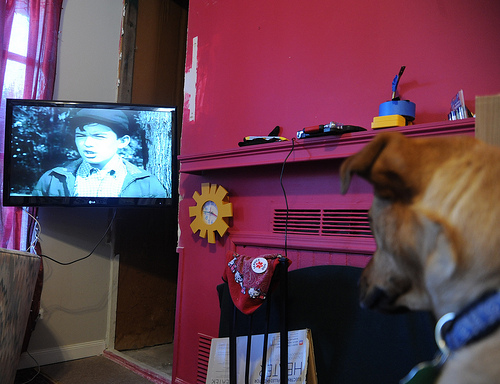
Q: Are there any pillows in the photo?
A: No, there are no pillows.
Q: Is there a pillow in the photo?
A: No, there are no pillows.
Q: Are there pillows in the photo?
A: No, there are no pillows.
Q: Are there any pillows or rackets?
A: No, there are no pillows or rackets.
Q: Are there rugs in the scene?
A: No, there are no rugs.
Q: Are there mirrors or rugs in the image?
A: No, there are no rugs or mirrors.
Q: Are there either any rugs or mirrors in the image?
A: No, there are no rugs or mirrors.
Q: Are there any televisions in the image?
A: Yes, there is a television.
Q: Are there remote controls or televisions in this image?
A: Yes, there is a television.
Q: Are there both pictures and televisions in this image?
A: No, there is a television but no pictures.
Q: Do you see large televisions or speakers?
A: Yes, there is a large television.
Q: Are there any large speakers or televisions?
A: Yes, there is a large television.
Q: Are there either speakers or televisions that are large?
A: Yes, the television is large.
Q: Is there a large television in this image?
A: Yes, there is a large television.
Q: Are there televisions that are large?
A: Yes, there is a television that is large.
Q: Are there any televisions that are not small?
A: Yes, there is a large television.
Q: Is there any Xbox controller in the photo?
A: No, there are no Xbox controllers.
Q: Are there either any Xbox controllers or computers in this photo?
A: No, there are no Xbox controllers or computers.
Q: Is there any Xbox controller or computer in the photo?
A: No, there are no Xbox controllers or computers.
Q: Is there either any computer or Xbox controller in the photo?
A: No, there are no Xbox controllers or computers.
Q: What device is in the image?
A: The device is a television.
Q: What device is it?
A: The device is a television.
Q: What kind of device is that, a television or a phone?
A: This is a television.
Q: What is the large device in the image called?
A: The device is a television.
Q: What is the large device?
A: The device is a television.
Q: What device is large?
A: The device is a television.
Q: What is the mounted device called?
A: The device is a television.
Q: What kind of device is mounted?
A: The device is a television.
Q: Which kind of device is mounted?
A: The device is a television.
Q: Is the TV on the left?
A: Yes, the TV is on the left of the image.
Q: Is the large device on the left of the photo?
A: Yes, the TV is on the left of the image.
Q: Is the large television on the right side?
A: No, the TV is on the left of the image.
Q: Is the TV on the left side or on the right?
A: The TV is on the left of the image.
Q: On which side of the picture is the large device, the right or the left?
A: The TV is on the left of the image.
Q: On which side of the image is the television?
A: The television is on the left of the image.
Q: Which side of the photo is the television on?
A: The television is on the left of the image.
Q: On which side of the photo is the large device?
A: The television is on the left of the image.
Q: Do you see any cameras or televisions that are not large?
A: No, there is a television but it is large.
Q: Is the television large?
A: Yes, the television is large.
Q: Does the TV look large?
A: Yes, the TV is large.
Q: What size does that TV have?
A: The TV has large size.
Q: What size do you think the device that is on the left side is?
A: The TV is large.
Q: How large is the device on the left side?
A: The television is large.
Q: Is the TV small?
A: No, the TV is large.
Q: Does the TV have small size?
A: No, the TV is large.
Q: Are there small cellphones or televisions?
A: No, there is a television but it is large.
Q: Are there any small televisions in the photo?
A: No, there is a television but it is large.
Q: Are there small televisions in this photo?
A: No, there is a television but it is large.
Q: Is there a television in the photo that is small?
A: No, there is a television but it is large.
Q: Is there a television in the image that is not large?
A: No, there is a television but it is large.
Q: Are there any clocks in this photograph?
A: Yes, there is a clock.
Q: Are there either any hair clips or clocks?
A: Yes, there is a clock.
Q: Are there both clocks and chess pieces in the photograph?
A: No, there is a clock but no chess pieces.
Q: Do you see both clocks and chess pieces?
A: No, there is a clock but no chess pieces.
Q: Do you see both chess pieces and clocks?
A: No, there is a clock but no chess pieces.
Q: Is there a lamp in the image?
A: No, there are no lamps.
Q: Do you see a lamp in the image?
A: No, there are no lamps.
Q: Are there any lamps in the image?
A: No, there are no lamps.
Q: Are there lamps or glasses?
A: No, there are no lamps or glasses.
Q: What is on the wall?
A: The clock is on the wall.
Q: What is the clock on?
A: The clock is on the wall.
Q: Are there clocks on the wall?
A: Yes, there is a clock on the wall.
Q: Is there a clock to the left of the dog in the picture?
A: Yes, there is a clock to the left of the dog.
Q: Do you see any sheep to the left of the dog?
A: No, there is a clock to the left of the dog.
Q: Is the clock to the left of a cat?
A: No, the clock is to the left of the dog.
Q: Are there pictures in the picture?
A: No, there are no pictures.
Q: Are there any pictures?
A: No, there are no pictures.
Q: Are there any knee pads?
A: No, there are no knee pads.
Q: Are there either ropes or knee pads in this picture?
A: No, there are no knee pads or ropes.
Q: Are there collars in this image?
A: Yes, there is a collar.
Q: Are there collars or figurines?
A: Yes, there is a collar.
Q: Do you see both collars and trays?
A: No, there is a collar but no trays.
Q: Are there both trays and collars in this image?
A: No, there is a collar but no trays.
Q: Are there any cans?
A: No, there are no cans.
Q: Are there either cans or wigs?
A: No, there are no cans or wigs.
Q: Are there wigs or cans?
A: No, there are no cans or wigs.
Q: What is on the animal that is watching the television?
A: The collar is on the dog.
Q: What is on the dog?
A: The collar is on the dog.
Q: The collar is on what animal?
A: The collar is on the dog.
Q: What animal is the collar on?
A: The collar is on the dog.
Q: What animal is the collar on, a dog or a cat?
A: The collar is on a dog.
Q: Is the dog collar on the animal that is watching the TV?
A: Yes, the collar is on the dog.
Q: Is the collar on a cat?
A: No, the collar is on the dog.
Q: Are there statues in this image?
A: No, there are no statues.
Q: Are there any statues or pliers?
A: No, there are no statues or pliers.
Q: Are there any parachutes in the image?
A: No, there are no parachutes.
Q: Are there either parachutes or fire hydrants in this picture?
A: No, there are no parachutes or fire hydrants.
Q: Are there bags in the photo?
A: Yes, there is a bag.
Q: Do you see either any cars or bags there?
A: Yes, there is a bag.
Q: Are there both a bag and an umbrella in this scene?
A: No, there is a bag but no umbrellas.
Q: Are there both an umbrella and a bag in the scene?
A: No, there is a bag but no umbrellas.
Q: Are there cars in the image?
A: No, there are no cars.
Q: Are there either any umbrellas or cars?
A: No, there are no cars or umbrellas.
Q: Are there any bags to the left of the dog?
A: Yes, there is a bag to the left of the dog.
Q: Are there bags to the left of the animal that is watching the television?
A: Yes, there is a bag to the left of the dog.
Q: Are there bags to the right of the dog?
A: No, the bag is to the left of the dog.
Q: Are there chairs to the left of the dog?
A: No, there is a bag to the left of the dog.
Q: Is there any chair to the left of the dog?
A: No, there is a bag to the left of the dog.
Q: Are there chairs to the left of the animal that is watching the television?
A: No, there is a bag to the left of the dog.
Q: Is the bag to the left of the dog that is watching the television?
A: Yes, the bag is to the left of the dog.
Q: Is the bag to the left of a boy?
A: No, the bag is to the left of the dog.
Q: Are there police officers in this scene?
A: No, there are no police officers.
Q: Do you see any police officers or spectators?
A: No, there are no police officers or spectators.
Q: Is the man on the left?
A: Yes, the man is on the left of the image.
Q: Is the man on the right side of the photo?
A: No, the man is on the left of the image.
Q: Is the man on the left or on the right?
A: The man is on the left of the image.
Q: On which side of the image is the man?
A: The man is on the left of the image.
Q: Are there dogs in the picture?
A: Yes, there is a dog.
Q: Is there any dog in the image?
A: Yes, there is a dog.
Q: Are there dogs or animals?
A: Yes, there is a dog.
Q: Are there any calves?
A: No, there are no calves.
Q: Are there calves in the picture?
A: No, there are no calves.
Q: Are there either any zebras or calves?
A: No, there are no calves or zebras.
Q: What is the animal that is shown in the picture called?
A: The animal is a dog.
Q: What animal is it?
A: The animal is a dog.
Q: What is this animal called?
A: This is a dog.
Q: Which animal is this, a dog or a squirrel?
A: This is a dog.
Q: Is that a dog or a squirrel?
A: That is a dog.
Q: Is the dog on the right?
A: Yes, the dog is on the right of the image.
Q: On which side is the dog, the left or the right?
A: The dog is on the right of the image.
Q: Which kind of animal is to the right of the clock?
A: The animal is a dog.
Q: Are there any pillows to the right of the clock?
A: No, there is a dog to the right of the clock.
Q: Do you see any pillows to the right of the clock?
A: No, there is a dog to the right of the clock.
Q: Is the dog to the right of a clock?
A: Yes, the dog is to the right of a clock.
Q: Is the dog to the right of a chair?
A: No, the dog is to the right of a clock.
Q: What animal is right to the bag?
A: The animal is a dog.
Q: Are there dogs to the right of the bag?
A: Yes, there is a dog to the right of the bag.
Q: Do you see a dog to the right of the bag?
A: Yes, there is a dog to the right of the bag.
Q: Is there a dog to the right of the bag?
A: Yes, there is a dog to the right of the bag.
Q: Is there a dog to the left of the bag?
A: No, the dog is to the right of the bag.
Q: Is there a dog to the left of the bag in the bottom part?
A: No, the dog is to the right of the bag.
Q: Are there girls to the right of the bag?
A: No, there is a dog to the right of the bag.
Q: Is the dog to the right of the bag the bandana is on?
A: Yes, the dog is to the right of the bag.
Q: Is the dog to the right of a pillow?
A: No, the dog is to the right of the bag.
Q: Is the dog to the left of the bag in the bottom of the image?
A: No, the dog is to the right of the bag.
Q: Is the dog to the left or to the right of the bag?
A: The dog is to the right of the bag.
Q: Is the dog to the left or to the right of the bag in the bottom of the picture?
A: The dog is to the right of the bag.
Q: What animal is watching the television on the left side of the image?
A: The dog is watching the TV.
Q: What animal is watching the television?
A: The dog is watching the TV.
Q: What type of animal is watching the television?
A: The animal is a dog.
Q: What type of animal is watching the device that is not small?
A: The animal is a dog.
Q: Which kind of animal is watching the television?
A: The animal is a dog.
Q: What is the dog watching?
A: The dog is watching the TV.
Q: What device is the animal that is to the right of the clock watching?
A: The dog is watching the TV.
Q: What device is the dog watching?
A: The dog is watching the TV.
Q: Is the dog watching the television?
A: Yes, the dog is watching the television.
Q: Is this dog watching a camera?
A: No, the dog is watching the television.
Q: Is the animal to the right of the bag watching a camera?
A: No, the dog is watching the television.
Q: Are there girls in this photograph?
A: No, there are no girls.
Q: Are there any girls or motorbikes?
A: No, there are no girls or motorbikes.